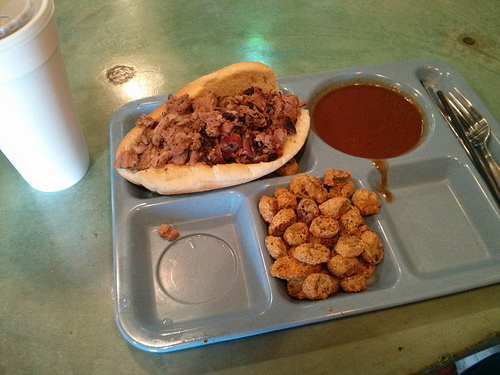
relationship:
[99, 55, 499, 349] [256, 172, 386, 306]
tray has breadcrumbs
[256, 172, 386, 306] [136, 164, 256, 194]
breadcrumbs are from bread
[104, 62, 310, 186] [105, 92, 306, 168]
sandwich has meat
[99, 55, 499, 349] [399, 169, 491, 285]
tray has empty part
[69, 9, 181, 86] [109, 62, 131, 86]
table has dent